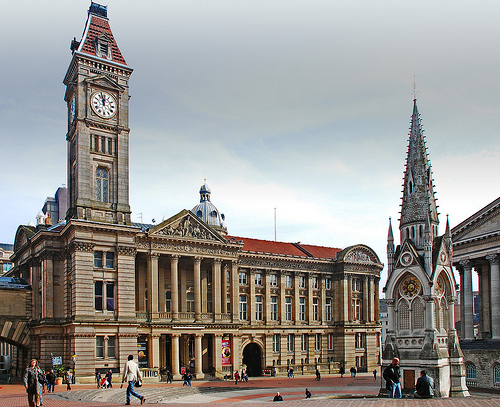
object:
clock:
[89, 90, 120, 119]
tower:
[62, 0, 132, 218]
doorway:
[242, 338, 265, 378]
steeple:
[403, 73, 429, 174]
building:
[379, 73, 470, 398]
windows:
[96, 167, 110, 202]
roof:
[221, 236, 344, 262]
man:
[415, 370, 436, 398]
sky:
[0, 0, 500, 294]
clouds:
[334, 20, 402, 60]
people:
[24, 359, 44, 407]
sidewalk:
[278, 374, 383, 378]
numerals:
[95, 106, 99, 109]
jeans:
[124, 381, 142, 404]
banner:
[222, 340, 230, 365]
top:
[123, 360, 143, 381]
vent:
[70, 37, 80, 56]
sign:
[139, 351, 147, 358]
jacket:
[24, 369, 42, 387]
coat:
[122, 361, 142, 382]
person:
[382, 356, 403, 398]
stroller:
[94, 377, 108, 389]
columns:
[148, 252, 159, 319]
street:
[0, 376, 500, 407]